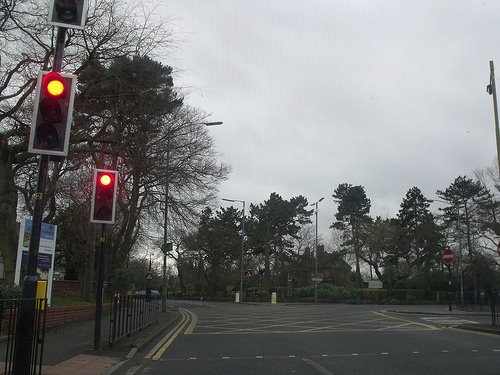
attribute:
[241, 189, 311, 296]
trees — tall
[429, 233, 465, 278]
sign — red, street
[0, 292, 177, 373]
sidewalk — brick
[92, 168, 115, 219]
light — traffic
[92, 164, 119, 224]
traffic light — red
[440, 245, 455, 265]
sign — caution, posted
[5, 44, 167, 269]
raffic signal — Metal 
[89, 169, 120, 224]
light — red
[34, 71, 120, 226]
lights — traffic, on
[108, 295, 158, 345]
railing — black 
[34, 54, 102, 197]
sign — red, white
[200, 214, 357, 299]
leaves — green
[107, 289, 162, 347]
fence — black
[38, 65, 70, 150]
light — red, stop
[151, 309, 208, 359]
lines — yellow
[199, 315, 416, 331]
lines — yellow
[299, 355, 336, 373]
lines — yellow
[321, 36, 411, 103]
cloud — gray